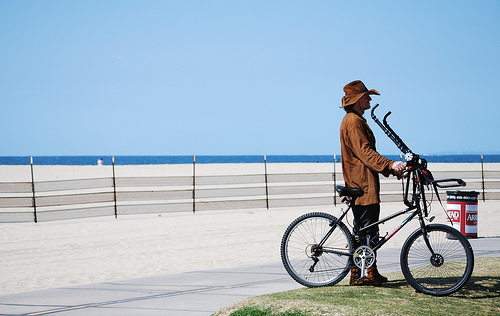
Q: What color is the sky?
A: Blue.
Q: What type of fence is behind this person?
A: A see-through fence.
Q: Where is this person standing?
A: Near a beach path.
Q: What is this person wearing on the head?
A: A hat.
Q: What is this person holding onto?
A: A bicycle.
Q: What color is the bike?
A: Black.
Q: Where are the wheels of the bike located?
A: On a patch of grass.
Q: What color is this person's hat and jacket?
A: Light brown.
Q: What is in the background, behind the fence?
A: The oceanfront.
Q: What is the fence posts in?
A: Sand.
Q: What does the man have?
A: Bike.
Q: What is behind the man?
A: Fence.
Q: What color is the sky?
A: Blue.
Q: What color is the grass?
A: Green.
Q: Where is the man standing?
A: On the grass.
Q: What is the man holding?
A: A bike.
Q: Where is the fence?
A: On the beach.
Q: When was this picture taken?
A: During the daytime.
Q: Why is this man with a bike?
A: He is going for a ride.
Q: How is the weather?
A: Clear.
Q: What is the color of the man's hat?
A: Brown.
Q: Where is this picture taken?
A: By the beach.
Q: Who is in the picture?
A: A man.